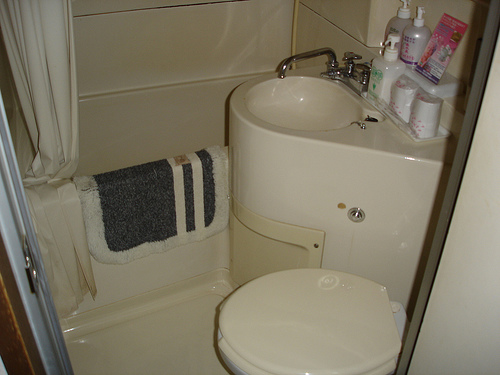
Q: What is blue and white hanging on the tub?
A: Bathroom rug.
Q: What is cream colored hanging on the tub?
A: A shower curtain.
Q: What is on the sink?
A: Multiple bathroom supplies.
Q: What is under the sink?
A: Storage.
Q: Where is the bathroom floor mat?
A: On the tub.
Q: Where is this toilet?
A: In an RV.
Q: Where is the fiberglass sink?
A: By the tub.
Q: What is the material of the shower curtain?
A: Vinyl.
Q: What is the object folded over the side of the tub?
A: Bath Mat.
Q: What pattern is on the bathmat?
A: White with grayish blue stripes.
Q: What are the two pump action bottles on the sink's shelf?
A: Shampoo and conditioner.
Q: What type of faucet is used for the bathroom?
A: Regular sized chrome faucet.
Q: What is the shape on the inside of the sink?
A: Round and circular.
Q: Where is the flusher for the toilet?
A: On the side of the sink.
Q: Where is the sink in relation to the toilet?
A: It is all one piece.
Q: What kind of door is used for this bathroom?
A: Sliding.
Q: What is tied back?
A: Shower curtain.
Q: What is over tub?
A: White tile.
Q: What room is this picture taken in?
A: Bathroom.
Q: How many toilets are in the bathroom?
A: One.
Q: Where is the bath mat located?
A: Bath ledge.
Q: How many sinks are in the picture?
A: One.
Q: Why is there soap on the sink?
A: Wash hands.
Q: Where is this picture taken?
A: Inside a house or apartment.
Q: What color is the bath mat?
A: Navy and cream.